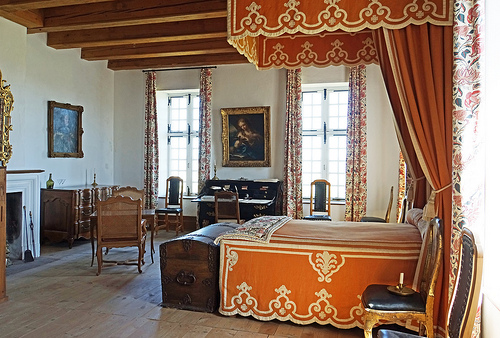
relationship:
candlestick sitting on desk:
[181, 152, 236, 197] [187, 130, 308, 237]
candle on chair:
[398, 271, 405, 286] [360, 210, 439, 336]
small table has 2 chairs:
[89, 209, 157, 262] [89, 181, 157, 277]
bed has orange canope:
[225, 203, 449, 328] [225, 0, 449, 227]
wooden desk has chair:
[194, 193, 269, 219] [211, 191, 239, 225]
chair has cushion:
[357, 217, 484, 336] [358, 280, 423, 311]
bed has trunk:
[220, 26, 452, 327] [159, 216, 240, 313]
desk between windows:
[191, 179, 282, 229] [161, 79, 348, 203]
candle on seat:
[396, 269, 404, 291] [358, 281, 425, 313]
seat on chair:
[358, 281, 425, 313] [363, 214, 443, 335]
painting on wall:
[216, 103, 274, 170] [110, 67, 283, 218]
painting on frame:
[216, 103, 274, 170] [215, 101, 276, 169]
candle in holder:
[398, 271, 405, 286] [388, 282, 414, 297]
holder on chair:
[388, 282, 414, 297] [358, 220, 443, 334]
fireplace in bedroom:
[0, 167, 47, 263] [5, 5, 482, 333]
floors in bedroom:
[26, 252, 102, 294] [5, 5, 482, 333]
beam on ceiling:
[44, 6, 245, 33] [27, 2, 227, 66]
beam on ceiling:
[80, 41, 252, 63] [27, 2, 227, 66]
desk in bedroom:
[196, 179, 282, 229] [5, 5, 482, 333]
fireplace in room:
[0, 167, 47, 263] [2, 5, 492, 333]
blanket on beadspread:
[210, 216, 291, 247] [214, 217, 422, 328]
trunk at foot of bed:
[159, 194, 294, 306] [219, 197, 419, 282]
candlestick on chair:
[388, 272, 416, 296] [341, 228, 498, 333]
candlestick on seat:
[388, 272, 416, 296] [362, 280, 421, 307]